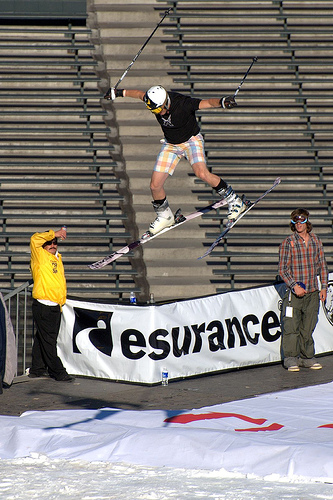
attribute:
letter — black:
[221, 310, 246, 351]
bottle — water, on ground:
[158, 368, 176, 386]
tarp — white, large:
[114, 376, 328, 493]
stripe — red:
[163, 412, 284, 432]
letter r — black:
[189, 319, 206, 353]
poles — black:
[81, 1, 299, 138]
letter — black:
[117, 328, 151, 366]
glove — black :
[221, 94, 242, 112]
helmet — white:
[139, 78, 169, 117]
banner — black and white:
[56, 272, 330, 381]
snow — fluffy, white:
[0, 457, 331, 499]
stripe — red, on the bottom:
[163, 410, 267, 425]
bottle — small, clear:
[122, 350, 199, 425]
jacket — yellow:
[14, 217, 90, 304]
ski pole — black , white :
[229, 46, 268, 91]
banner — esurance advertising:
[29, 270, 324, 401]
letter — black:
[171, 323, 193, 361]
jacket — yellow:
[31, 251, 64, 304]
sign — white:
[55, 273, 323, 384]